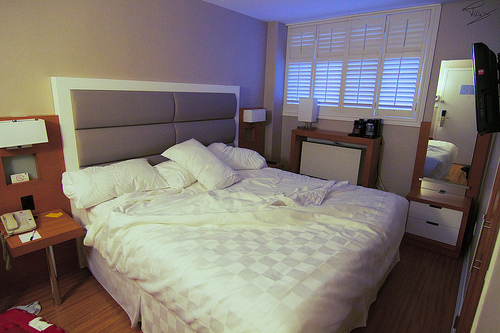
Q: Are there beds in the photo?
A: Yes, there is a bed.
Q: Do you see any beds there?
A: Yes, there is a bed.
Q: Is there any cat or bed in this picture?
A: Yes, there is a bed.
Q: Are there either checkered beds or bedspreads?
A: Yes, there is a checkered bed.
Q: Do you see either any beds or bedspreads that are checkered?
A: Yes, the bed is checkered.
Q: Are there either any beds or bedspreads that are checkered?
A: Yes, the bed is checkered.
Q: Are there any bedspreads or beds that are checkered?
A: Yes, the bed is checkered.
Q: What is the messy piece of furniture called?
A: The piece of furniture is a bed.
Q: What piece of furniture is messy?
A: The piece of furniture is a bed.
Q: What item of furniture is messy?
A: The piece of furniture is a bed.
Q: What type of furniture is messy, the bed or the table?
A: The bed is messy.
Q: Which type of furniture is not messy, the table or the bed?
A: The table is not messy.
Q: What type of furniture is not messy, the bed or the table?
A: The table is not messy.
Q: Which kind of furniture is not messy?
A: The furniture is a table.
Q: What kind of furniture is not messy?
A: The furniture is a table.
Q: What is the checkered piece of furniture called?
A: The piece of furniture is a bed.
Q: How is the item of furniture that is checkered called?
A: The piece of furniture is a bed.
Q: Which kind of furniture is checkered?
A: The furniture is a bed.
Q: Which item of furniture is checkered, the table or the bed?
A: The bed is checkered.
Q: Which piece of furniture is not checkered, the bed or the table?
A: The table is not checkered.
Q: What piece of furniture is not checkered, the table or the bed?
A: The table is not checkered.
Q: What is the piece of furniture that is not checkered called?
A: The piece of furniture is a table.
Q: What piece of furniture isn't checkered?
A: The piece of furniture is a table.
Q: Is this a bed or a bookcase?
A: This is a bed.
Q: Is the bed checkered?
A: Yes, the bed is checkered.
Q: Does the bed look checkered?
A: Yes, the bed is checkered.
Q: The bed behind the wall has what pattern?
A: The bed is checkered.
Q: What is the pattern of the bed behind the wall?
A: The bed is checkered.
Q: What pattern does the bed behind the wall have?
A: The bed has checkered pattern.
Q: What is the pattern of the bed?
A: The bed is checkered.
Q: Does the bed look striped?
A: No, the bed is checkered.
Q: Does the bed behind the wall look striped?
A: No, the bed is checkered.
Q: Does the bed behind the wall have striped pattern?
A: No, the bed is checkered.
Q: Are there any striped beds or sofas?
A: No, there is a bed but it is checkered.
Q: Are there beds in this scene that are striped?
A: No, there is a bed but it is checkered.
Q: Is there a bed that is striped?
A: No, there is a bed but it is checkered.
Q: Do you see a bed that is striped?
A: No, there is a bed but it is checkered.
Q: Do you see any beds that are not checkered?
A: No, there is a bed but it is checkered.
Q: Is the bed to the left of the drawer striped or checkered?
A: The bed is checkered.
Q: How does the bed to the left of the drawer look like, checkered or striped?
A: The bed is checkered.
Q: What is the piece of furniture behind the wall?
A: The piece of furniture is a bed.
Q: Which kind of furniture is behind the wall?
A: The piece of furniture is a bed.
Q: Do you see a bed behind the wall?
A: Yes, there is a bed behind the wall.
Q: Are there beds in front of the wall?
A: No, the bed is behind the wall.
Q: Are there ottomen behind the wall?
A: No, there is a bed behind the wall.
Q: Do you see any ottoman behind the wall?
A: No, there is a bed behind the wall.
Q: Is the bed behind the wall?
A: Yes, the bed is behind the wall.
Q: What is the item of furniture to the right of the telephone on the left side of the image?
A: The piece of furniture is a bed.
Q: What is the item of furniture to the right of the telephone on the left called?
A: The piece of furniture is a bed.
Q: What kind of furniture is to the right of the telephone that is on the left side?
A: The piece of furniture is a bed.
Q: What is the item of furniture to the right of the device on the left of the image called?
A: The piece of furniture is a bed.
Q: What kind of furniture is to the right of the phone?
A: The piece of furniture is a bed.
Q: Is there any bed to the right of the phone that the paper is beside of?
A: Yes, there is a bed to the right of the telephone.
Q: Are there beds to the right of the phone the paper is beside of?
A: Yes, there is a bed to the right of the telephone.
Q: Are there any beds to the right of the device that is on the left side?
A: Yes, there is a bed to the right of the telephone.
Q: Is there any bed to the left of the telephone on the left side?
A: No, the bed is to the right of the phone.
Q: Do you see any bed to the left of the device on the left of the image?
A: No, the bed is to the right of the phone.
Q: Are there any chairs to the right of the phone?
A: No, there is a bed to the right of the phone.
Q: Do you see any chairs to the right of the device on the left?
A: No, there is a bed to the right of the phone.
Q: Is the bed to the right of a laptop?
A: No, the bed is to the right of a phone.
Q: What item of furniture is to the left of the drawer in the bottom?
A: The piece of furniture is a bed.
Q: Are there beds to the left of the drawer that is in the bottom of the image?
A: Yes, there is a bed to the left of the drawer.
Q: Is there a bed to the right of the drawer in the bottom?
A: No, the bed is to the left of the drawer.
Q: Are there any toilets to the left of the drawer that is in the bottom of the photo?
A: No, there is a bed to the left of the drawer.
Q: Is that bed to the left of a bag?
A: No, the bed is to the left of the drawer.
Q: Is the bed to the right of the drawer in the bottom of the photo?
A: No, the bed is to the left of the drawer.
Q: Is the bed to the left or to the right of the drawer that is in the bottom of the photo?
A: The bed is to the left of the drawer.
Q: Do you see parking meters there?
A: No, there are no parking meters.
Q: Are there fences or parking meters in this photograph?
A: No, there are no parking meters or fences.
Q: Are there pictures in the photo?
A: No, there are no pictures.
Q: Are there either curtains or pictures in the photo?
A: No, there are no pictures or curtains.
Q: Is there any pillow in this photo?
A: Yes, there is a pillow.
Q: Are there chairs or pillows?
A: Yes, there is a pillow.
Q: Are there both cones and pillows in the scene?
A: No, there is a pillow but no cones.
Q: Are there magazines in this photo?
A: No, there are no magazines.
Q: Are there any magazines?
A: No, there are no magazines.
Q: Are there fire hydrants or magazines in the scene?
A: No, there are no magazines or fire hydrants.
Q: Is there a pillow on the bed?
A: Yes, there is a pillow on the bed.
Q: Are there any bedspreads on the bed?
A: No, there is a pillow on the bed.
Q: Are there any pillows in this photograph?
A: Yes, there is a pillow.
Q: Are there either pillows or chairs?
A: Yes, there is a pillow.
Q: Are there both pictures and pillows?
A: No, there is a pillow but no pictures.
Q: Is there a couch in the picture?
A: No, there are no couches.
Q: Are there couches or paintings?
A: No, there are no couches or paintings.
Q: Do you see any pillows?
A: Yes, there is a pillow.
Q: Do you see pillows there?
A: Yes, there is a pillow.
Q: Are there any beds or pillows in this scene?
A: Yes, there is a pillow.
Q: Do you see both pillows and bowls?
A: No, there is a pillow but no bowls.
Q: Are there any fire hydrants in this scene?
A: No, there are no fire hydrants.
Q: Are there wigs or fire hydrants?
A: No, there are no fire hydrants or wigs.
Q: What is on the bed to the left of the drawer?
A: The pillow is on the bed.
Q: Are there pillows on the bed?
A: Yes, there is a pillow on the bed.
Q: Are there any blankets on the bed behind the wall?
A: No, there is a pillow on the bed.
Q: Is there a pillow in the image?
A: Yes, there is a pillow.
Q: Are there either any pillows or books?
A: Yes, there is a pillow.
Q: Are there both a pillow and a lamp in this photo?
A: Yes, there are both a pillow and a lamp.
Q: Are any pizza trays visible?
A: No, there are no pizza trays.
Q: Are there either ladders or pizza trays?
A: No, there are no pizza trays or ladders.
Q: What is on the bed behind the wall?
A: The pillow is on the bed.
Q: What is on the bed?
A: The pillow is on the bed.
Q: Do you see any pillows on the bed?
A: Yes, there is a pillow on the bed.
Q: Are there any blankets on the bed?
A: No, there is a pillow on the bed.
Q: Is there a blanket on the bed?
A: No, there is a pillow on the bed.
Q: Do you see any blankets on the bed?
A: No, there is a pillow on the bed.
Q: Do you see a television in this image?
A: Yes, there is a television.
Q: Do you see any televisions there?
A: Yes, there is a television.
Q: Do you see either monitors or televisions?
A: Yes, there is a television.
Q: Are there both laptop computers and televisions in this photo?
A: No, there is a television but no laptops.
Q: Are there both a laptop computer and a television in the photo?
A: No, there is a television but no laptops.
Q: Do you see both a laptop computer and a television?
A: No, there is a television but no laptops.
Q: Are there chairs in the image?
A: No, there are no chairs.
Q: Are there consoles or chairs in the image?
A: No, there are no chairs or consoles.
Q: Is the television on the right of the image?
A: Yes, the television is on the right of the image.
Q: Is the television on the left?
A: No, the television is on the right of the image.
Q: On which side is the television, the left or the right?
A: The television is on the right of the image.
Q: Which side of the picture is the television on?
A: The television is on the right of the image.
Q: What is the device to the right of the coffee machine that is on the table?
A: The device is a television.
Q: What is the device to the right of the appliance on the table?
A: The device is a television.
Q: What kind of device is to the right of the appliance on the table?
A: The device is a television.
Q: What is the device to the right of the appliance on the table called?
A: The device is a television.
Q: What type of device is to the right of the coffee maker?
A: The device is a television.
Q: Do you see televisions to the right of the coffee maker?
A: Yes, there is a television to the right of the coffee maker.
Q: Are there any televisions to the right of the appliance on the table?
A: Yes, there is a television to the right of the coffee maker.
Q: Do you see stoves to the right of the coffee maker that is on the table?
A: No, there is a television to the right of the coffee maker.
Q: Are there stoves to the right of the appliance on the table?
A: No, there is a television to the right of the coffee maker.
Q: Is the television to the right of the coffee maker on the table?
A: Yes, the television is to the right of the coffee maker.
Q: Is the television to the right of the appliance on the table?
A: Yes, the television is to the right of the coffee maker.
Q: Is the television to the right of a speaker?
A: No, the television is to the right of the coffee maker.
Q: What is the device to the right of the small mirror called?
A: The device is a television.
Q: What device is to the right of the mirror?
A: The device is a television.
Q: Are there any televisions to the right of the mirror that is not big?
A: Yes, there is a television to the right of the mirror.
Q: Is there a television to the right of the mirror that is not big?
A: Yes, there is a television to the right of the mirror.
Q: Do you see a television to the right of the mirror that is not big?
A: Yes, there is a television to the right of the mirror.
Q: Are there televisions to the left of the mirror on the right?
A: No, the television is to the right of the mirror.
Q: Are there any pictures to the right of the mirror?
A: No, there is a television to the right of the mirror.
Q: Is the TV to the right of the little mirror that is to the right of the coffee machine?
A: Yes, the TV is to the right of the mirror.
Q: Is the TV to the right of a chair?
A: No, the TV is to the right of the mirror.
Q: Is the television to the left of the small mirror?
A: No, the television is to the right of the mirror.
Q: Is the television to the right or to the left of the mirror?
A: The television is to the right of the mirror.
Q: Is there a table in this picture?
A: Yes, there is a table.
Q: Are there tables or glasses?
A: Yes, there is a table.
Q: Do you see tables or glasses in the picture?
A: Yes, there is a table.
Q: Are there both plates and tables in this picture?
A: No, there is a table but no plates.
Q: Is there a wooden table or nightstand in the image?
A: Yes, there is a wood table.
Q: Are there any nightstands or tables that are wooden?
A: Yes, the table is wooden.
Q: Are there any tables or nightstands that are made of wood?
A: Yes, the table is made of wood.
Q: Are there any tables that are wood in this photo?
A: Yes, there is a wood table.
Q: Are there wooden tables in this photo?
A: Yes, there is a wood table.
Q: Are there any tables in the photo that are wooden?
A: Yes, there is a wood table.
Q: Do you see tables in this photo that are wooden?
A: Yes, there is a table that is wooden.